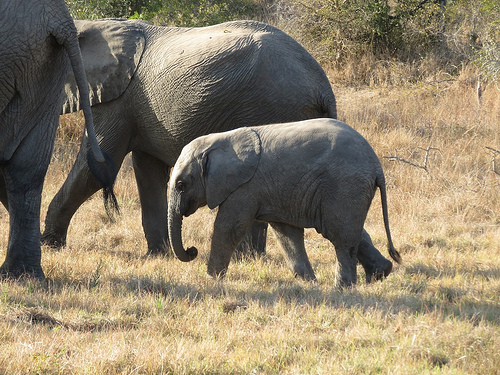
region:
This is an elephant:
[160, 120, 442, 298]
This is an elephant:
[41, 4, 346, 286]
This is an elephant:
[0, 0, 127, 292]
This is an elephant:
[156, 114, 436, 314]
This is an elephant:
[27, 9, 345, 301]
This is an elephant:
[161, 105, 427, 300]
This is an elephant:
[36, 8, 351, 290]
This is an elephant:
[159, 130, 423, 325]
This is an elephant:
[0, 3, 135, 303]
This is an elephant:
[141, 114, 426, 321]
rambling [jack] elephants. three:
[0, 0, 430, 302]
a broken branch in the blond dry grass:
[378, 129, 445, 184]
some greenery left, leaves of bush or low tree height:
[66, 0, 276, 37]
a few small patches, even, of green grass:
[0, 264, 499, 374]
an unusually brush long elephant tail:
[77, 130, 137, 235]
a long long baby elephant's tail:
[372, 154, 407, 277]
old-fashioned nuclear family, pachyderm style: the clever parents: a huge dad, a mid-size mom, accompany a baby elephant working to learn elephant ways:
[0, 0, 425, 296]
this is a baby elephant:
[132, 94, 388, 312]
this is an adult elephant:
[42, 15, 339, 256]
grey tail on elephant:
[357, 151, 422, 289]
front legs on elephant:
[188, 190, 325, 297]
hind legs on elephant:
[303, 211, 401, 301]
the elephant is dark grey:
[134, 82, 393, 301]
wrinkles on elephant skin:
[14, 15, 62, 144]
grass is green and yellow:
[77, 255, 434, 370]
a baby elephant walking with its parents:
[3, 4, 495, 349]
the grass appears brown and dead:
[5, 78, 499, 363]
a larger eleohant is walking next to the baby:
[66, 10, 336, 281]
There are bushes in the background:
[63, 3, 498, 91]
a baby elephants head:
[156, 131, 236, 271]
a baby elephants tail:
[368, 165, 418, 270]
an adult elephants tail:
[43, 14, 131, 217]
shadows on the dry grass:
[51, 257, 496, 334]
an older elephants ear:
[58, 18, 150, 118]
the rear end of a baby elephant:
[289, 129, 406, 283]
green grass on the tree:
[476, 6, 485, 46]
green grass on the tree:
[473, 33, 495, 59]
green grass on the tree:
[325, 15, 363, 45]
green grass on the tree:
[359, 6, 401, 45]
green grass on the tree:
[170, 9, 215, 17]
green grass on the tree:
[140, 6, 177, 23]